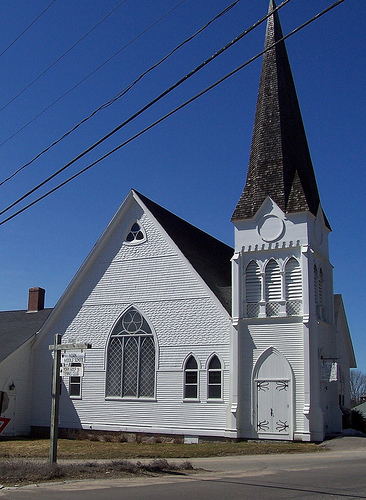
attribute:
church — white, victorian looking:
[1, 3, 357, 447]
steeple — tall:
[229, 2, 356, 444]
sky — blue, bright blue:
[1, 0, 365, 403]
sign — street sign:
[58, 347, 87, 376]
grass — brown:
[3, 426, 332, 488]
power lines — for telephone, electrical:
[1, 1, 337, 226]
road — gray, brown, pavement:
[3, 436, 365, 499]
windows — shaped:
[205, 351, 222, 404]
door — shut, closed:
[247, 347, 300, 442]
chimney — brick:
[25, 279, 46, 315]